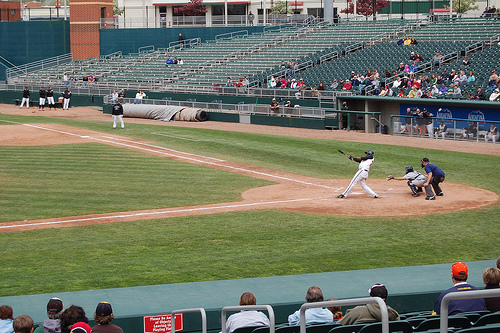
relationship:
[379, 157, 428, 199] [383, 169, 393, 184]
catcher reaching ball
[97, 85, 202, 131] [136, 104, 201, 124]
rolls of tarp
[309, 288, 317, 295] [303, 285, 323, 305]
bald spot on head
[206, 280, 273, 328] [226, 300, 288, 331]
man wearing shirt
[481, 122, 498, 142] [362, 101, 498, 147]
players in dugout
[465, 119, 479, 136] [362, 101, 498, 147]
players in dugout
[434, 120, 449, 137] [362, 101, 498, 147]
players in dugout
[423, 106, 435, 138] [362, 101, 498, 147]
players in dugout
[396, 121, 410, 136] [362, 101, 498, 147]
players in dugout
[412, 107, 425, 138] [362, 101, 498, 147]
coach in dugout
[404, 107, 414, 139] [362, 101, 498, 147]
coaches in dugout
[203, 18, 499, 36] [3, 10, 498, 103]
empty seats in stands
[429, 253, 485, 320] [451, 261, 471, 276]
man wearing cap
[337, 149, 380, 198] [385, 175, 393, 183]
baseball player swinging ball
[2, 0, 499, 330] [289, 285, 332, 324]
baseball game has spectator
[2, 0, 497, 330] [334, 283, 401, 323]
baseball game has spectator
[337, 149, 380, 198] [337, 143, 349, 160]
baseball player has bat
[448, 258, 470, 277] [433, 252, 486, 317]
cap on spectator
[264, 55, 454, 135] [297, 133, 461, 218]
seats in sand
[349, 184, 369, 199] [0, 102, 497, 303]
home plate on field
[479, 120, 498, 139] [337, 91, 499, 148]
player in dugout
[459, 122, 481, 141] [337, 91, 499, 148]
player in dugout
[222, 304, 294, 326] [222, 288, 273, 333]
shirt on man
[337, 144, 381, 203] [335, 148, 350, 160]
baseball player swinging bat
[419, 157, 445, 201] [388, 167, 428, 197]
spectator squatting behind catcher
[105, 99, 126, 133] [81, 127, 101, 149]
ball player near base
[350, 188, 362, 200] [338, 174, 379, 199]
plate between legs